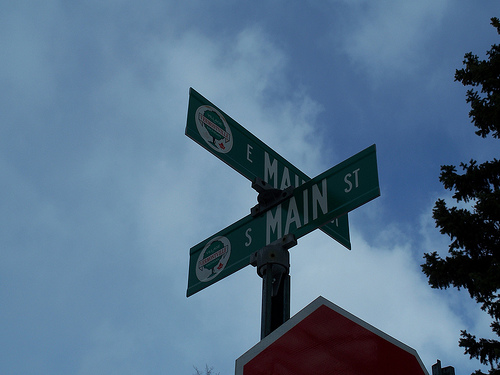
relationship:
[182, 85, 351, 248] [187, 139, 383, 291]
street sign perpendicular to street sign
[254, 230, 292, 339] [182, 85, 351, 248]
iron pole supports street sign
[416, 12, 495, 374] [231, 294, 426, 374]
tree next to stop sign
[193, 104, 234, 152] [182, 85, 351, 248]
circular logo on street sign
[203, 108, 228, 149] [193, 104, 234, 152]
tree inside circular logo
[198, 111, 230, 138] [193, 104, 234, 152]
letters in circular logo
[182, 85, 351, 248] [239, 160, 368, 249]
street sign says s main st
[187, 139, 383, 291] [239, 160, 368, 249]
street sign says s main st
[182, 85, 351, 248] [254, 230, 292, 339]
street sign atop iron pole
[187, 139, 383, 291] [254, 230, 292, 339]
street sign atop iron pole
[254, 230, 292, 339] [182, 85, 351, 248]
iron pole holds street sign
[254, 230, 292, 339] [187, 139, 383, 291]
iron pole holds street sign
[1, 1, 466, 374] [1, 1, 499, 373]
cloud in sky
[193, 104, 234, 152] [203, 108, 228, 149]
circular logo has tree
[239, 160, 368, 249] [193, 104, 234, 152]
s main st has circular logo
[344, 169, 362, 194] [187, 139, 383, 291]
letters st printed on street sign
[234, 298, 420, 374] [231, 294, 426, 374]
border around stop sign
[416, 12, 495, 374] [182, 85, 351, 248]
tree next to street sign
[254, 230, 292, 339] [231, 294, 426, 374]
iron pole behind stop sign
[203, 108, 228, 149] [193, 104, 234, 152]
tree on circular logo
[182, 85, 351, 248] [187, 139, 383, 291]
street sign crosses street sign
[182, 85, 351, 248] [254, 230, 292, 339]
street sign on iron pole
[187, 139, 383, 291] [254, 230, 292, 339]
street sign on iron pole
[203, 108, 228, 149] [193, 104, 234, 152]
tree in circular logo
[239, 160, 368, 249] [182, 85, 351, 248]
s main st on street sign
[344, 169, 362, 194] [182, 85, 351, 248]
letters st on street sign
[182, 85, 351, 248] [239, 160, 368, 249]
street sign depicting s main st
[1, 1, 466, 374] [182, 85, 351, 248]
cloud behind street sign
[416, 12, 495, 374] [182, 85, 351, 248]
tree near street sign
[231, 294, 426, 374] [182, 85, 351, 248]
stop sign below street sign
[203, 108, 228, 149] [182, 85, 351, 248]
tree on street sign